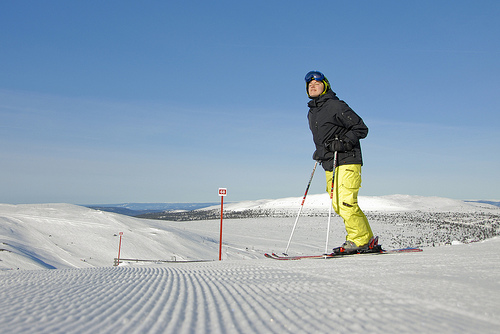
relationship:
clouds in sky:
[15, 139, 478, 203] [3, 2, 499, 207]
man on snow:
[298, 67, 385, 258] [3, 199, 496, 326]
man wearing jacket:
[298, 67, 385, 258] [306, 97, 367, 166]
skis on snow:
[269, 242, 424, 264] [3, 199, 496, 326]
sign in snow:
[217, 183, 232, 258] [3, 199, 496, 326]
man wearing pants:
[298, 67, 385, 258] [330, 163, 373, 248]